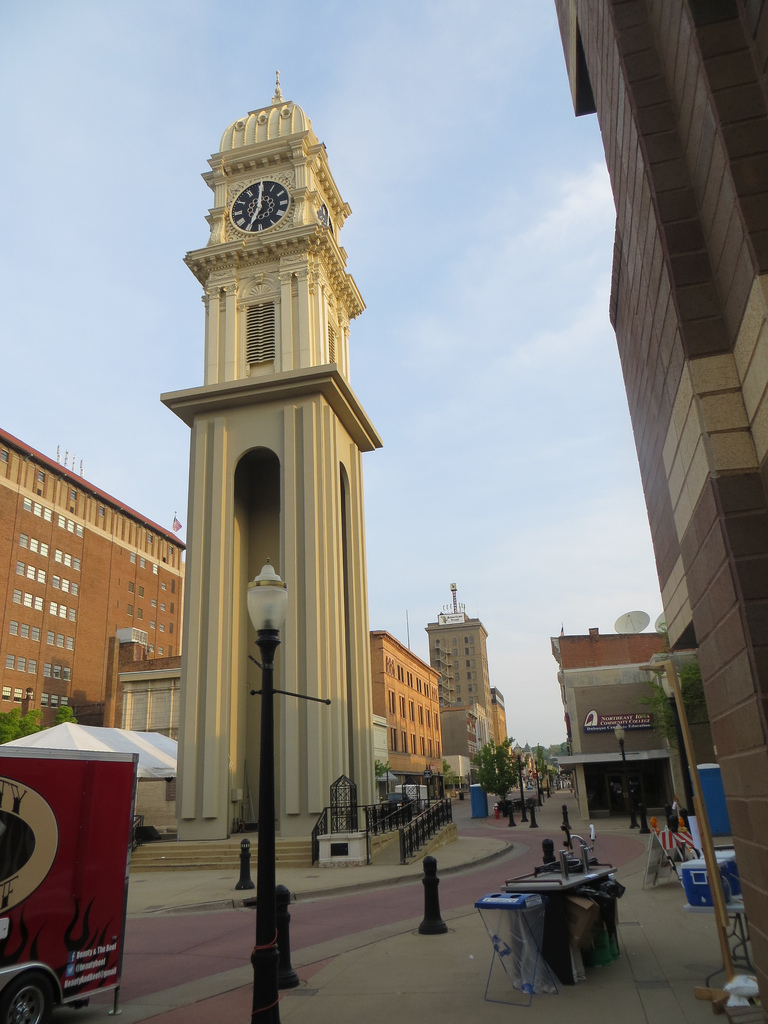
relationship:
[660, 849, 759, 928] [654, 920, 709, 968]
cooler on sidewalk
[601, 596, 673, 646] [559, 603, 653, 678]
dish on roof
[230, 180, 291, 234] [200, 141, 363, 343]
clock at top of tower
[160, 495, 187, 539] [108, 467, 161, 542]
flag on roof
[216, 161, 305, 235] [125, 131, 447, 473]
clock on tower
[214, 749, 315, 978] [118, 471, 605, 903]
light post in city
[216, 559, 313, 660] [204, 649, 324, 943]
lamp on post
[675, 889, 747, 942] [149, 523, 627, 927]
table in city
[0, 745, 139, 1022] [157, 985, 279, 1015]
red trailer on sidewalk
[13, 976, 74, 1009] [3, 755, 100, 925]
tire on trailer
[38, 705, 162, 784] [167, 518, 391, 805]
tent near tower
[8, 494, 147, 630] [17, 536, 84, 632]
windows on building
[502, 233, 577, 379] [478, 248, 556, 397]
clouds in sky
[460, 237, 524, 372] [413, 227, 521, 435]
clouds in sky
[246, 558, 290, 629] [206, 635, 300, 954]
lamp on pole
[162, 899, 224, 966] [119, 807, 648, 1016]
red brick on street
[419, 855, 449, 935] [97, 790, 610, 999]
metal pole near road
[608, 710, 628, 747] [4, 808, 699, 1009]
street light on side of street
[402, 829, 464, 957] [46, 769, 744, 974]
metal pole on street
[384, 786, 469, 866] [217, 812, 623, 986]
railing on pathway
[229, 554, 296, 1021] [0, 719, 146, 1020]
lamp post next to trailer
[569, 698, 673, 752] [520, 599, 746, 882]
sign on building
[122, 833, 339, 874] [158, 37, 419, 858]
stone steps leading to clocktower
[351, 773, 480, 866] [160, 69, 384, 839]
ramp leading up to tower